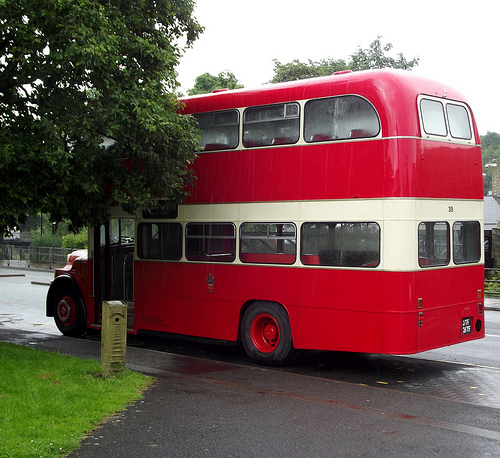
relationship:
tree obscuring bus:
[4, 0, 209, 254] [44, 66, 481, 354]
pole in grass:
[100, 297, 132, 380] [3, 336, 153, 455]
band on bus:
[117, 202, 497, 276] [44, 66, 481, 354]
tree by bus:
[4, 5, 208, 253] [36, 57, 493, 377]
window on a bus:
[413, 218, 453, 269] [44, 66, 481, 354]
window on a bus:
[449, 219, 482, 269] [44, 66, 481, 354]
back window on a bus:
[416, 93, 476, 144] [44, 66, 481, 354]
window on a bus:
[235, 218, 301, 266] [44, 66, 481, 354]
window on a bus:
[183, 219, 235, 267] [44, 66, 481, 354]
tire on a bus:
[240, 295, 290, 360] [44, 66, 481, 354]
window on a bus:
[242, 102, 302, 147] [44, 66, 481, 354]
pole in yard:
[100, 297, 132, 380] [13, 334, 162, 439]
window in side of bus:
[297, 216, 382, 278] [44, 66, 481, 354]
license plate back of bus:
[452, 314, 477, 334] [44, 66, 481, 354]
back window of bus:
[416, 93, 476, 144] [36, 57, 493, 377]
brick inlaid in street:
[363, 352, 484, 416] [123, 348, 476, 447]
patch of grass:
[12, 342, 149, 435] [12, 340, 149, 436]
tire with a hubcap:
[241, 298, 291, 362] [250, 313, 279, 351]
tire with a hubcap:
[45, 287, 81, 336] [55, 292, 75, 329]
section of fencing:
[11, 240, 68, 266] [15, 237, 56, 269]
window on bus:
[449, 219, 482, 269] [44, 66, 489, 367]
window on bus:
[413, 218, 453, 269] [44, 66, 489, 367]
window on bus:
[302, 95, 377, 136] [44, 66, 489, 367]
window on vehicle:
[241, 220, 307, 262] [46, 77, 482, 385]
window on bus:
[302, 222, 382, 265] [44, 66, 489, 367]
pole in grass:
[100, 297, 132, 380] [9, 340, 147, 453]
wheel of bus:
[44, 280, 90, 335] [36, 57, 493, 377]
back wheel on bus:
[238, 300, 292, 365] [44, 66, 481, 354]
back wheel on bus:
[238, 300, 292, 365] [36, 57, 493, 377]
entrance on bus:
[87, 202, 137, 328] [36, 57, 493, 377]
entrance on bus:
[87, 202, 137, 328] [44, 66, 481, 354]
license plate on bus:
[452, 314, 477, 334] [44, 66, 481, 354]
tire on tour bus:
[237, 298, 294, 368] [44, 65, 488, 368]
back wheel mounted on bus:
[238, 300, 292, 365] [44, 66, 481, 354]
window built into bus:
[297, 216, 382, 278] [44, 66, 481, 354]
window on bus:
[297, 216, 382, 278] [44, 66, 489, 367]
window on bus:
[416, 215, 447, 269] [44, 66, 489, 367]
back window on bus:
[416, 93, 476, 144] [44, 66, 489, 367]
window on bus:
[141, 220, 183, 258] [44, 66, 489, 367]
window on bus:
[244, 102, 293, 147] [44, 66, 489, 367]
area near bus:
[3, 343, 142, 455] [36, 57, 493, 377]